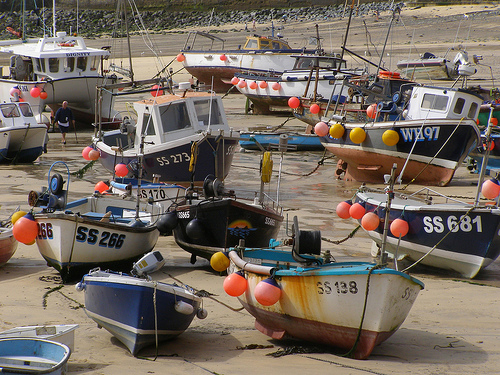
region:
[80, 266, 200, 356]
blue boat on top of sand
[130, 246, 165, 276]
motor on top of boat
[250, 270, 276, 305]
pink buoy hanging from boat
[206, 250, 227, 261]
round yellow buoy hanging from boat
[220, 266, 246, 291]
buoy next to buoy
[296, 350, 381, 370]
line on top of sand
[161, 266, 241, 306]
rope on top of sand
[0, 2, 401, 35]
rocks behind sand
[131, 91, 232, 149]
cabin on a blue boat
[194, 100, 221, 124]
window on cabin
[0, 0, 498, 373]
Boats on the sand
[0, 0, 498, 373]
Boats are on the sand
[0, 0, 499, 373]
Boats on the beach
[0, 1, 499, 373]
Boats are on the beach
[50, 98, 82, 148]
Person on the sand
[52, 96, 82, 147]
Person is on the sand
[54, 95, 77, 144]
Person on the beach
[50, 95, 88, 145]
Person is on the beach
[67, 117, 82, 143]
Person carrying a walking stick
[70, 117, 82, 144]
Person is carrying a walking stick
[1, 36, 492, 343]
Large number of boats on the beach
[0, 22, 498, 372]
Dry sand under boats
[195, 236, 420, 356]
Boat Named S5138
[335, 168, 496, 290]
Blue and white boat identified as SS681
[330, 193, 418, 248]
Four balloons on side of boat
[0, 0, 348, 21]
Green grass and rocks in the background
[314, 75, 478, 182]
Blue, white, and brown boat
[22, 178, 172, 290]
Boat identified as SS266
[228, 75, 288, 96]
Four orange balloons side by side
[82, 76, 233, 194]
Dark blue and white boat identified as SS273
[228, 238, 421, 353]
boat on the ground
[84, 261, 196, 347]
boat on the ground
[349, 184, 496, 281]
boat on the ground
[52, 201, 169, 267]
boat on the ground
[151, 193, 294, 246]
boat on the ground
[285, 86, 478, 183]
boat on the ground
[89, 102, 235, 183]
boat on the ground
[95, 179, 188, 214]
boat on the ground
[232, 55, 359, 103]
boat on the ground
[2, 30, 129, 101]
boat on the ground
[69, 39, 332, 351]
several boats are parked on the dock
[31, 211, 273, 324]
all of the boat names precede with "ss"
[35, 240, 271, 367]
the boat is blue and white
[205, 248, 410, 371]
the boat is white and rusted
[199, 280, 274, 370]
the ground is covered with dirt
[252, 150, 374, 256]
water is on the ground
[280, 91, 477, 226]
balloons adorn the boat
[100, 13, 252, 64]
rocks are in the background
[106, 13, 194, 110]
the sails are on the boat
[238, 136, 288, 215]
yellow rope is on the boat